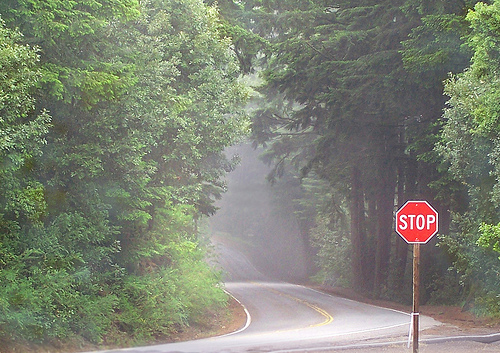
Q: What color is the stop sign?
A: Red.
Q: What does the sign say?
A: Stop.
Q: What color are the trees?
A: Green.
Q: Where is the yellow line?
A: On the road.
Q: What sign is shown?
A: Stop sign.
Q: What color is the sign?
A: Red.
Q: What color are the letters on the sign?
A: White.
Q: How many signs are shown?
A: One.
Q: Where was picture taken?
A: Country road.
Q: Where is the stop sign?
A: On a pole.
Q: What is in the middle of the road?
A: Yellow lines.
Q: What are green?
A: Trees.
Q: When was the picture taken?
A: During the daytime.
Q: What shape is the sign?
A: Octagon.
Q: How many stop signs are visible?
A: 1.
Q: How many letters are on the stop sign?
A: 4.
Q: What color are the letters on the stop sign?
A: White.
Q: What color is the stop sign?
A: Red.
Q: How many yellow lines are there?
A: 2.